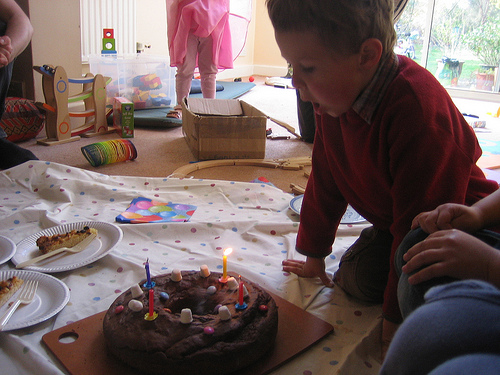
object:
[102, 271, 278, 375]
cake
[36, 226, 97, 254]
pie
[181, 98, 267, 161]
box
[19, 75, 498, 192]
floor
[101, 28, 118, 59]
blocks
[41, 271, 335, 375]
plate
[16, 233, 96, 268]
fork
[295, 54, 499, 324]
shirt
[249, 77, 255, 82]
ball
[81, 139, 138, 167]
toy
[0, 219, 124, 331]
plates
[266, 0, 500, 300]
boy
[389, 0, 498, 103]
doors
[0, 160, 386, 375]
cloth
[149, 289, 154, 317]
candle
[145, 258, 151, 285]
candlei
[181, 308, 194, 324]
marshmallow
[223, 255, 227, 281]
candle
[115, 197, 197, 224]
napkin